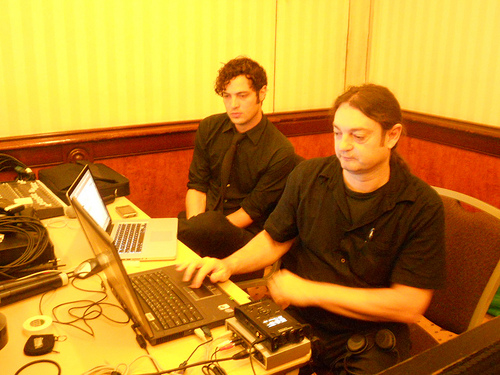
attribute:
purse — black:
[3, 333, 63, 363]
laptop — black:
[55, 185, 247, 348]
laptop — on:
[53, 160, 183, 269]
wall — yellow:
[24, 16, 184, 101]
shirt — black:
[181, 113, 299, 220]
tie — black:
[217, 124, 246, 214]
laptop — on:
[61, 158, 188, 267]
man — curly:
[168, 51, 302, 261]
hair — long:
[330, 78, 404, 125]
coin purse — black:
[21, 331, 67, 358]